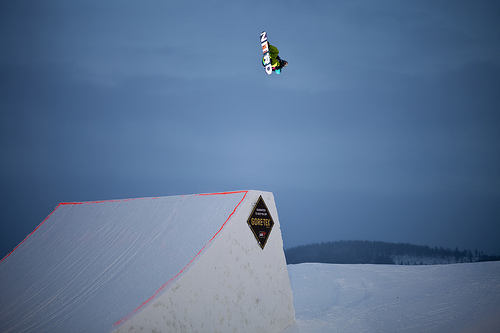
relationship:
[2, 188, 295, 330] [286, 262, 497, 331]
ramp in snow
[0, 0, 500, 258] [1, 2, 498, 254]
cloud in sky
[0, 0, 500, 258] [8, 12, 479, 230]
cloud in blue sky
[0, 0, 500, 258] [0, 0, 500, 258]
cloud in blue sky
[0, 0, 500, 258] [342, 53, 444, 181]
cloud in blue sky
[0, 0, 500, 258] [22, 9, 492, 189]
cloud in sky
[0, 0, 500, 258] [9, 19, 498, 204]
cloud in sky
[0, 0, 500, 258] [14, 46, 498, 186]
cloud in sky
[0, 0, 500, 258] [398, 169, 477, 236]
cloud in sky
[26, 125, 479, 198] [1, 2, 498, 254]
cloud in sky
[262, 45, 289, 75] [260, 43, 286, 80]
man dressed in gear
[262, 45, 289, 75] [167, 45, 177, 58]
man in air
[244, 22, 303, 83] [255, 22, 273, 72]
man on snowboard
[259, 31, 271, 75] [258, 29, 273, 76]
"nitro" on snowboard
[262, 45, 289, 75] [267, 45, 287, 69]
man wearing gear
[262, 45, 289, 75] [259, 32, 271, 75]
man on snowboard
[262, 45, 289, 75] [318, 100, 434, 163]
man in air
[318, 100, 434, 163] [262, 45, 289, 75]
air around man